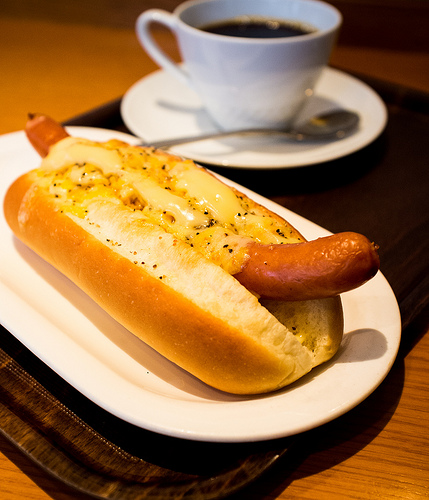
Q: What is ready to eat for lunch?
A: A hot dog.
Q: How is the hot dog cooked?
A: Well done.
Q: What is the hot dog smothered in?
A: Cheese and spices.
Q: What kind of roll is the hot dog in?
A: Toasted.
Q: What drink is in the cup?
A: Hot black coffee.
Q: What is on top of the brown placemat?
A: A white plate.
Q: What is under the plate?
A: Wooden table.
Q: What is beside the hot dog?
A: White cup and saucer.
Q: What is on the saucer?
A: Silver coffee spoon.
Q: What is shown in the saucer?
A: The cup's shadow.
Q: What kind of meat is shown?
A: Hot dog.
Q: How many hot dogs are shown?
A: 1.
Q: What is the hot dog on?
A: Bun.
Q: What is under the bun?
A: Plate.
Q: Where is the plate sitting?
A: Tray.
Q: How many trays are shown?
A: 1.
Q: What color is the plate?
A: White.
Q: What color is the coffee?
A: Black.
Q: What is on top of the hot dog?
A: Cheese.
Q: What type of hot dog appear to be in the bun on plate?
A: Foot- long hot dog.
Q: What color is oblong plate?
A: White.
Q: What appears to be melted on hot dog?
A: Cheese.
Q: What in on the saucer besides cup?
A: Spoon.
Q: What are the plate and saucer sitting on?
A: Tray.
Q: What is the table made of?
A: Wood.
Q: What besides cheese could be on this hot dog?
A: Mustard.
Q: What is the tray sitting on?
A: Table.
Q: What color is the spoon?
A: Silver.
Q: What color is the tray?
A: Brown.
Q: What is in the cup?
A: Coffee.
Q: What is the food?
A: A hot dog.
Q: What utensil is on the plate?
A: A spoon.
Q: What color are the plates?
A: White.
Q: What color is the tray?
A: Black.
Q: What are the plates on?
A: A tray.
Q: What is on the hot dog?
A: Cheese.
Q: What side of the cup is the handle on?
A: The left.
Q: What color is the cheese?
A: Yellow.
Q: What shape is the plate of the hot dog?
A: Oval.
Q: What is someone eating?
A: A hotdog.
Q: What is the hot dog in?
A: A bun.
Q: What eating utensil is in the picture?
A: A teaspoon.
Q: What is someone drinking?
A: Coffee.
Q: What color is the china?
A: White.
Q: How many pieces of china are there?
A: Three.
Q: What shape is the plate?
A: Oval.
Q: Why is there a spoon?
A: To stir the coffee.